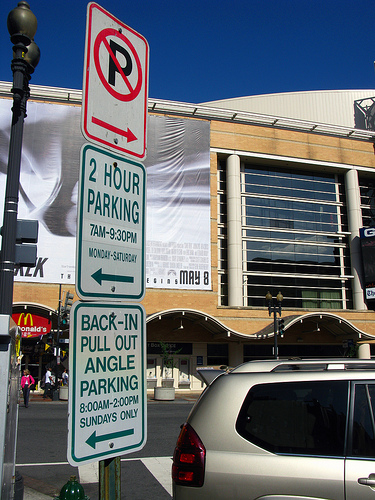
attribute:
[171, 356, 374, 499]
car — grey, metalic-colored, gray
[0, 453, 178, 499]
lines — white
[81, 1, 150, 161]
board — red, white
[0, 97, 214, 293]
banner — black, white, large, wrinkled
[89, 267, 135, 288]
arrow — green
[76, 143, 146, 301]
sign — green, white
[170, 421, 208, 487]
light — red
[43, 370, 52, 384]
t-shirt — white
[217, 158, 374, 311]
windows — large